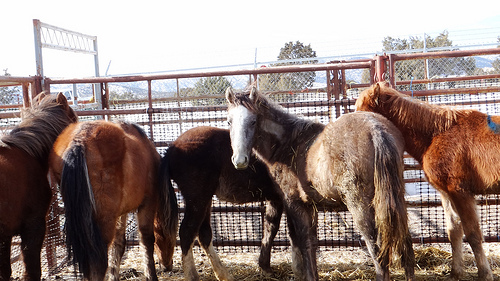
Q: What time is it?
A: Daytime.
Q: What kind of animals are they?
A: Horses.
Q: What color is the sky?
A: White.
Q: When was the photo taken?
A: Afternoon.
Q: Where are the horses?
A: Next to each other.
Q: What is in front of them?
A: A fence.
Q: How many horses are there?
A: Five.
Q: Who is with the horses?
A: No one.